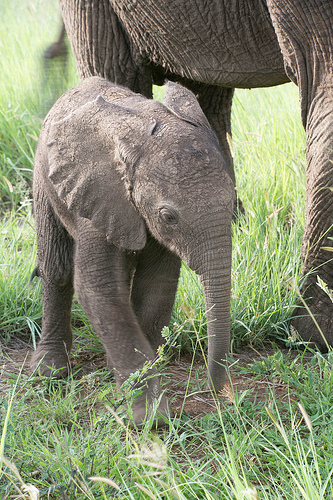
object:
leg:
[137, 253, 179, 360]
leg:
[72, 227, 165, 392]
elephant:
[35, 0, 332, 358]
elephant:
[25, 70, 240, 422]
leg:
[286, 68, 333, 316]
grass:
[0, 0, 308, 196]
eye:
[154, 203, 178, 228]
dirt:
[0, 335, 331, 465]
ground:
[0, 1, 331, 499]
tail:
[36, 20, 77, 98]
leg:
[172, 74, 248, 233]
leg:
[57, 1, 151, 98]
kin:
[285, 39, 317, 133]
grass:
[1, 340, 333, 500]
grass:
[0, 170, 306, 354]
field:
[0, 0, 331, 494]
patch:
[0, 347, 332, 432]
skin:
[199, 20, 257, 61]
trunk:
[185, 210, 230, 399]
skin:
[84, 161, 109, 194]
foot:
[117, 380, 174, 437]